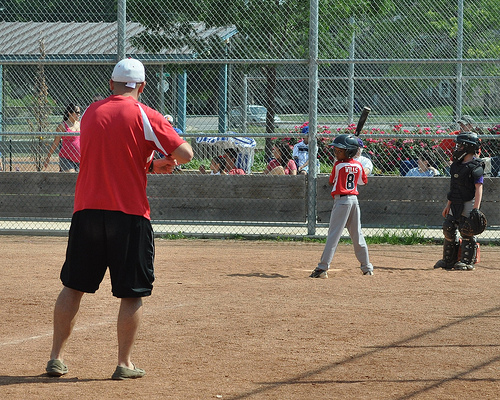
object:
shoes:
[309, 268, 329, 279]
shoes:
[453, 259, 480, 271]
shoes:
[46, 358, 69, 377]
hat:
[111, 58, 146, 89]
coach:
[46, 57, 193, 382]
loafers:
[109, 364, 146, 382]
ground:
[0, 228, 499, 399]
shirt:
[328, 158, 368, 197]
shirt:
[72, 96, 187, 221]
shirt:
[406, 167, 442, 177]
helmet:
[328, 133, 359, 159]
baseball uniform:
[60, 93, 188, 297]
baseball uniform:
[318, 156, 373, 271]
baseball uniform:
[447, 159, 485, 264]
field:
[1, 232, 498, 398]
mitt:
[461, 208, 487, 238]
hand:
[471, 213, 482, 226]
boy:
[431, 131, 484, 270]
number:
[346, 174, 354, 190]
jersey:
[329, 158, 368, 199]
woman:
[263, 137, 299, 175]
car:
[229, 103, 282, 130]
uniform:
[315, 157, 374, 271]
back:
[338, 164, 356, 192]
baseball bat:
[353, 105, 372, 136]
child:
[307, 132, 375, 279]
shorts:
[58, 209, 154, 299]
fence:
[0, 0, 499, 230]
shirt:
[59, 120, 84, 163]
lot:
[232, 150, 248, 172]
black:
[112, 218, 143, 270]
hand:
[442, 206, 450, 218]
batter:
[307, 134, 373, 277]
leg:
[318, 202, 347, 273]